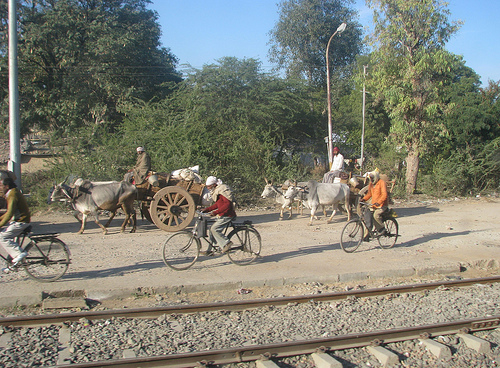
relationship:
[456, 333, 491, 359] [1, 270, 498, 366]
board on tracks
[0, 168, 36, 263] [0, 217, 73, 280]
man riding bicycle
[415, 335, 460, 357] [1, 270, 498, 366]
board on tracks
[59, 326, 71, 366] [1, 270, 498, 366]
board on tracks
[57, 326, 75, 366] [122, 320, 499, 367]
board on tracks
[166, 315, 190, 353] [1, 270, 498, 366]
board on tracks